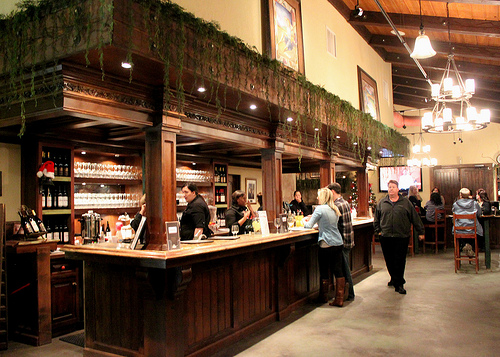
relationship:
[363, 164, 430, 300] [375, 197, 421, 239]
man walking shirt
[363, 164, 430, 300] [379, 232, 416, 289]
man walking pants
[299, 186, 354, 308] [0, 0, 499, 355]
woman standing bar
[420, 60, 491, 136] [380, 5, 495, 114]
chandelier hanging from ceiling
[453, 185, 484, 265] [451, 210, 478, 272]
person sitting on chair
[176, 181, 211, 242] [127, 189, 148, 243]
bartender talking to bartender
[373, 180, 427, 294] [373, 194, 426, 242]
man wearing jacket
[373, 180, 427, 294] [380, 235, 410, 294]
man wearing pants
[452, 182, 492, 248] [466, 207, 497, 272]
couple sitting at table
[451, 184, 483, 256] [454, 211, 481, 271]
person sitting in chair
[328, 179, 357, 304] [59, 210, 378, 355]
person standing at bar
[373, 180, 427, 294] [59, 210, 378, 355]
man walking in front of bar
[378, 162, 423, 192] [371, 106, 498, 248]
television hanging on wall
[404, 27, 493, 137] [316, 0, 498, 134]
lights hanging from ceiling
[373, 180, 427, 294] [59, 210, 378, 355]
man walking by bar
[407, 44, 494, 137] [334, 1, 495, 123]
chandelier hanging from ceiling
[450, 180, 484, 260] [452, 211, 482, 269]
person sitting in chair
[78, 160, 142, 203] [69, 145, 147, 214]
glasses on shelf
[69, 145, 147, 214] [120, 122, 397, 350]
shelf behind bar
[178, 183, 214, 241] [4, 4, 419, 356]
bartender behind bar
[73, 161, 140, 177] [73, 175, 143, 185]
glasses on shelf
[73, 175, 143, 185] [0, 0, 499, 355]
shelf at bar